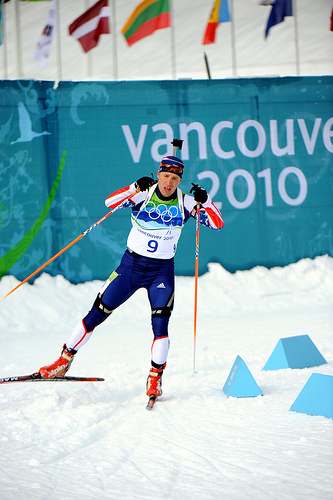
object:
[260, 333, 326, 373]
marker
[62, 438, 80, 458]
snow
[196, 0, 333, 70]
mountain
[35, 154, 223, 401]
man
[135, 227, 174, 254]
symbol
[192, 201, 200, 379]
poles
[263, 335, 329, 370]
triangle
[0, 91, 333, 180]
gate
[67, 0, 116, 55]
flags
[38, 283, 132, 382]
leg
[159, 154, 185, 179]
cap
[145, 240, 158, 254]
number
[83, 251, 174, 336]
pants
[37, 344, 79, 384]
shoes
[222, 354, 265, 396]
barriers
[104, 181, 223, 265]
shirt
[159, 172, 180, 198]
face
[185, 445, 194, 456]
ice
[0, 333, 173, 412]
skating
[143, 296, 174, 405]
legs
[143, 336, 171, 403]
shoe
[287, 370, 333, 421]
object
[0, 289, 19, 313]
sticks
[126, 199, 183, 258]
bib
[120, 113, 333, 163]
vancouver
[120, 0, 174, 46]
flag